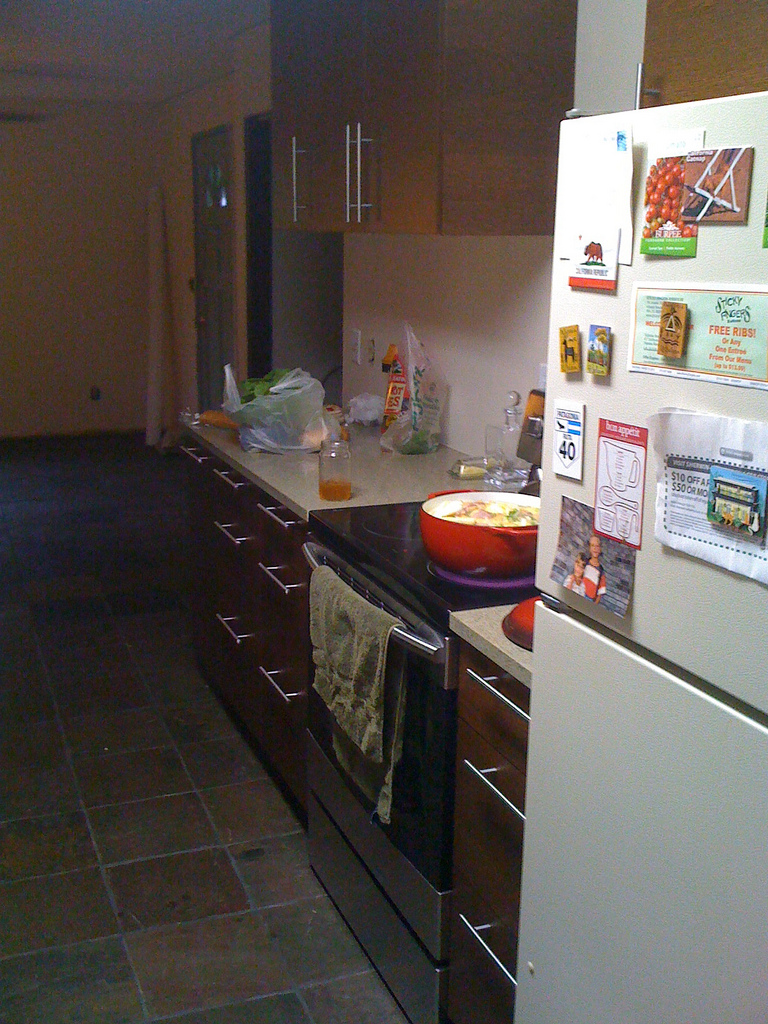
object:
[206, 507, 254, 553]
handle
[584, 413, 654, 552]
magnet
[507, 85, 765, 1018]
fridge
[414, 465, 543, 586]
bowl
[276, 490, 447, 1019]
stove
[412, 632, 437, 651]
silver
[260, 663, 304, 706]
handle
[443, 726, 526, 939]
drawer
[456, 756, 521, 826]
handle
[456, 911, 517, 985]
handle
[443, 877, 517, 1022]
drawer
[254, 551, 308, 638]
drawer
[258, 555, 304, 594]
handle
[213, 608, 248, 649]
handle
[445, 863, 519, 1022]
drawer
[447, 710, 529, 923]
drawer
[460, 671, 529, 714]
handle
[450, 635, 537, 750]
drawer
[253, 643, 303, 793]
drawer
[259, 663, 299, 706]
handle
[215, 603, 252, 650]
handle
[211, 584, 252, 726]
drawer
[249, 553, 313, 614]
handle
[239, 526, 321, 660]
drawer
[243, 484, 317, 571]
drawer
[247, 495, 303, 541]
handle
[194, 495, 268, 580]
drawer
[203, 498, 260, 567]
handle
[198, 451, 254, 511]
handle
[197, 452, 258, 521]
drawer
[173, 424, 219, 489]
drawer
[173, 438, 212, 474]
handle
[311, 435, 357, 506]
jar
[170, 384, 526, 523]
table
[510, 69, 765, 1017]
refrigerator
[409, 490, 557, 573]
pot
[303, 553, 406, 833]
towel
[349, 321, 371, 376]
outlet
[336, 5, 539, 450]
wall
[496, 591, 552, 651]
top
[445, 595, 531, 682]
table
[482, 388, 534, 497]
bottle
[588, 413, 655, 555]
paper